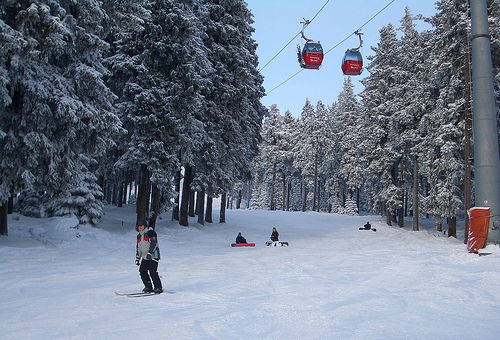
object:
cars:
[295, 39, 326, 70]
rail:
[258, 0, 332, 77]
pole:
[461, 46, 473, 247]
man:
[134, 220, 164, 293]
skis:
[126, 289, 167, 297]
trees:
[0, 0, 273, 236]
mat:
[466, 207, 489, 250]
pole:
[469, 2, 500, 242]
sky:
[231, 0, 440, 118]